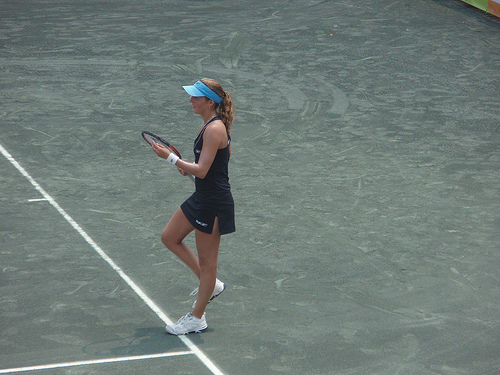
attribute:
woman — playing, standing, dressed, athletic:
[148, 73, 240, 337]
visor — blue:
[182, 73, 222, 105]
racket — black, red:
[139, 124, 202, 181]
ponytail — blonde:
[217, 91, 239, 120]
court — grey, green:
[2, 2, 498, 374]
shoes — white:
[165, 280, 229, 335]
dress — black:
[181, 117, 239, 236]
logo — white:
[195, 213, 212, 233]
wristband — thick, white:
[166, 148, 183, 168]